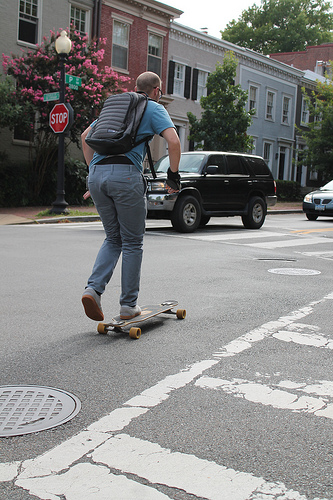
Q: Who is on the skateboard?
A: A man.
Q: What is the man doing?
A: Skating.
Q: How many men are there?
A: One.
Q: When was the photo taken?
A: Afternoon.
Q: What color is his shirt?
A: Blue.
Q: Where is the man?
A: On the street.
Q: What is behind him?
A: A sewer.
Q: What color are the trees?
A: Green.